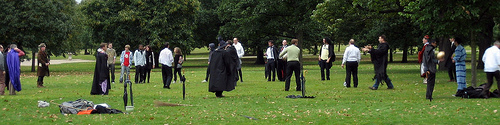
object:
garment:
[90, 49, 114, 95]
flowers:
[233, 100, 343, 118]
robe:
[204, 43, 243, 93]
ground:
[3, 60, 484, 120]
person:
[279, 39, 304, 92]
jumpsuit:
[450, 45, 467, 89]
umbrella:
[123, 81, 136, 110]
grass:
[0, 51, 498, 124]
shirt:
[121, 51, 130, 69]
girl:
[145, 46, 157, 83]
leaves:
[25, 100, 497, 125]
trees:
[0, 0, 500, 72]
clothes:
[59, 99, 124, 116]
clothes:
[8, 51, 24, 95]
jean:
[120, 63, 133, 82]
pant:
[147, 63, 152, 84]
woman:
[173, 46, 188, 84]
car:
[364, 45, 372, 57]